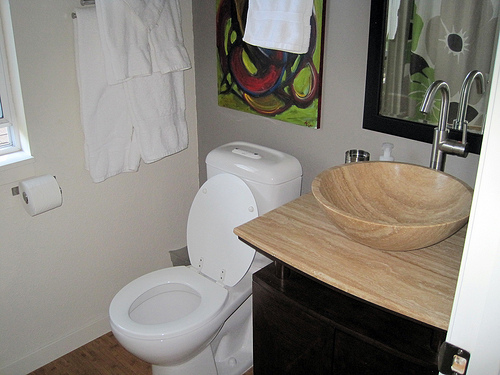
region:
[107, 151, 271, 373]
white toilet in bathroom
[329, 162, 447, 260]
brown bowl in sink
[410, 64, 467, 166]
brushed nickel faucet and handle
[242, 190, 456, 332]
wooden sink under bowl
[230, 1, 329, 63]
white towel above toilet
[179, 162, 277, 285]
toilet lid is raised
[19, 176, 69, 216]
toilet roll on silver holder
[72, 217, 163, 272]
white wall near toilet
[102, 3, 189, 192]
white towels on rack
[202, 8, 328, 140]
green painting behind towel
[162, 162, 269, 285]
lid of the toilet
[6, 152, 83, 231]
toilet paper roll in photo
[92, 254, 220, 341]
rim of the toilet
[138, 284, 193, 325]
inner part of the toilet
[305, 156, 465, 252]
bowl on the sink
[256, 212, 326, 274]
table under the bowl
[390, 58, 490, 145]
faucet in the photo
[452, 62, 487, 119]
faucet in the mirror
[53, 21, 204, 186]
towels on the wall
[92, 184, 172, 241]
white wall in photo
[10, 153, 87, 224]
roll of white toilet tissue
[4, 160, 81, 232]
silver tissue holder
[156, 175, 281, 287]
lid to white commode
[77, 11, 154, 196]
white terry cloth towel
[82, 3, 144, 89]
white terry cloth hand towel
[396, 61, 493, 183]
stainless steel water faucet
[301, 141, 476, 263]
wood look water basin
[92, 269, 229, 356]
clean white commode seat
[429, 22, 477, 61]
sunshine reflection in the mirror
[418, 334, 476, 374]
brass door latch on side of door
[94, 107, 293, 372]
this is a toilet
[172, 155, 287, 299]
toilet lid seat cover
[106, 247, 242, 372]
this is the seat of the toilet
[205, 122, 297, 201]
this is the commode lid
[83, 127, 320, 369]
the toilet is white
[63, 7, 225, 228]
white towels hanging on rack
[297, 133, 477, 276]
a wooden sink basin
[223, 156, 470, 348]
a wood sink counter top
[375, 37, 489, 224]
silver faucet of sink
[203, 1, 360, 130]
multicolored art on wall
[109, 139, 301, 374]
a white porcelain toilet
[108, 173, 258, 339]
a white plastic toilet seat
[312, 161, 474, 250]
a marble bowl sink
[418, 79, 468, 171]
a chrome bathroom faucet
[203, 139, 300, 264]
a white porcelain toilet tank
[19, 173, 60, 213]
a roll of toilet paper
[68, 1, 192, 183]
a white bathroom towel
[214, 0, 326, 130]
a colorful painting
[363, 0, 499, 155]
a black framed mirror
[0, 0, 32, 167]
a bathroom window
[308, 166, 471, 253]
a large wooden sink basin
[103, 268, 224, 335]
a white porcelain toilet seat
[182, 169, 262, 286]
a white toilet seat lid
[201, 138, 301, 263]
back of a toilet tank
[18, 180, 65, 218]
white roll of toilet paper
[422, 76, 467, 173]
large silver sink faucet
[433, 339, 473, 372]
grey metal door frame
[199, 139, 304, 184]
white toilet tank lid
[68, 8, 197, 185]
large white bath towels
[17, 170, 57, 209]
a roll of toilet paper